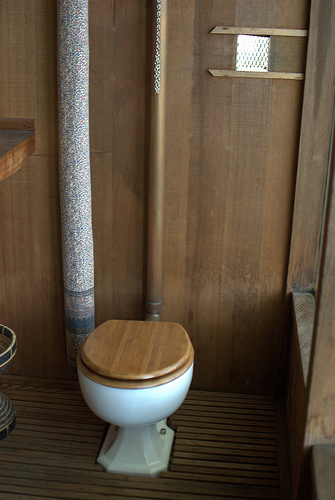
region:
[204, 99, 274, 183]
Wall is brown color.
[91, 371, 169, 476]
One toilet is seen.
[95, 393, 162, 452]
Toilet is white color.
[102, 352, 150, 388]
Seat is brown color.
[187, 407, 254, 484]
floor is brown color.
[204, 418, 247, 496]
Floor is made of wood.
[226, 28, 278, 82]
Mirror is attached to the wall.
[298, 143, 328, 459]
Window is brown color.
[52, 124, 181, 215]
Two pipe is running.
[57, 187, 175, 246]
Pipes are attached to the wall.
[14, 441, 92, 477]
this is afloor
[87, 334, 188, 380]
this is a toilet lid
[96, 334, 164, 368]
the lid is brown in color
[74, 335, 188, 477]
this is toilet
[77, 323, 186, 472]
the toilet is white and brown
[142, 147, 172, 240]
this is a water pipe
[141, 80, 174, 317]
the water pipe is brown in color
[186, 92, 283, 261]
these is a wall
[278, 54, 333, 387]
this is a window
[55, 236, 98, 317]
this is pipe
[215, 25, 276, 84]
small glass window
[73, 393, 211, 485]
porcelain base tiolet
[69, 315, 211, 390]
wooden-like toilet seat top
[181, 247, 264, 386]
brown wood panels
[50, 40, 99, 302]
long pole attached to wall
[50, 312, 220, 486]
toilet with white base and brown seat and top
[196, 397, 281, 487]
brown wood panels floorboards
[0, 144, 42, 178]
wooden shelf attached to wall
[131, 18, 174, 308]
pipe for tiolet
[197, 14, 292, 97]
window above tiolet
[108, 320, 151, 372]
this is a toilet seat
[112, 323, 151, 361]
the toilet seat is made of wood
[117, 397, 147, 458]
this is a toilet bowl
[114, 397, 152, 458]
the toilet bowl is white in color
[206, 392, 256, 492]
this is the floor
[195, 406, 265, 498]
the floor is wooden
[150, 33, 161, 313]
this is a pipe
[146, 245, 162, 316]
the pipe is metallic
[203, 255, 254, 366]
this is a wall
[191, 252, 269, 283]
the wall is brown in color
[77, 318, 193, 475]
this is a toilet sink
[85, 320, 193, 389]
the toilet sink is closed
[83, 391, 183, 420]
the toilet sink is white in color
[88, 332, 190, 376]
the toilet sink lid is white in brown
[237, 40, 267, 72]
this is a small opening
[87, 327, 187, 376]
the lid is wooden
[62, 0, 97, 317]
this is a pool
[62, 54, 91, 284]
the poll is white in color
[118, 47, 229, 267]
this is a wooden wall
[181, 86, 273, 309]
the wooden wall is brown in color